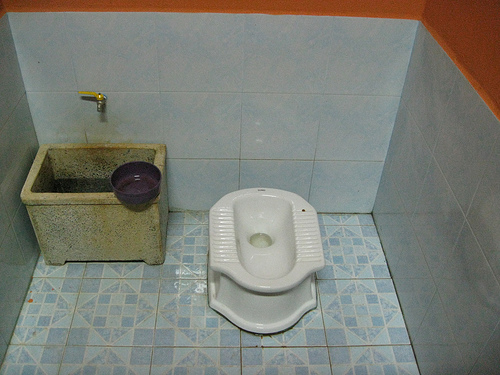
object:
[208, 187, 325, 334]
toilet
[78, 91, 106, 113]
faucet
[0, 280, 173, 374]
floor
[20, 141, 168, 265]
basin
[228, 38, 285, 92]
wall